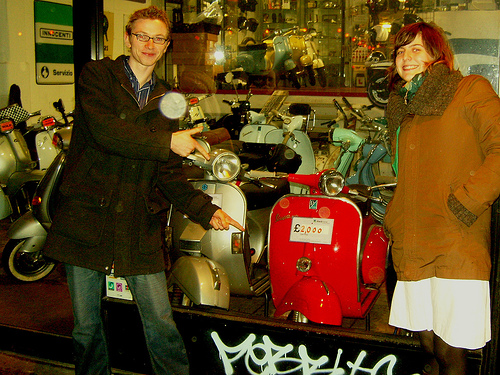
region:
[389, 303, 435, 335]
edge of short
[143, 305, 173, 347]
part of a trouser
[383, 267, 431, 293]
edge of a coat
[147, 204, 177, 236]
part of a pocket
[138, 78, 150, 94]
part of a collar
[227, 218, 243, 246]
part of a finger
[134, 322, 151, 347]
edge of a trouser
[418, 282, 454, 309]
part of a short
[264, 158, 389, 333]
a solid red motorcycle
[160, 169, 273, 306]
a silver motorcycle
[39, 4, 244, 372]
a man standing and pointing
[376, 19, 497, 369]
a woman standing and posing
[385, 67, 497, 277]
a brown winter jacket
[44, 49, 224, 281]
a brown winter jacket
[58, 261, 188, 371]
a pair of men's blue jeans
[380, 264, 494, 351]
a woman's white skirt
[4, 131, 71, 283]
a park silver motorcycle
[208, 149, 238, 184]
a motorcycle headlight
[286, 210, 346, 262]
The number tow thousand.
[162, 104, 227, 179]
The right hand of a man shaped like a gun while pointing.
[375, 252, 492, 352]
A white skirt worn by a woman.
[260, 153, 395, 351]
A red scooter for sale.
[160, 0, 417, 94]
A mirror hanging on the wall.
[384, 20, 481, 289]
The light brown coat worn by a woman.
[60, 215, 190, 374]
A pair of blue jeans being worn by a man.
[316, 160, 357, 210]
The headlight of the red scooter.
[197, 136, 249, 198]
The headlight of the scooter next to the red one.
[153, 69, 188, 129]
The random white circle that appears on top of the coat of the man.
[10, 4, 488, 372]
two people posing for the camera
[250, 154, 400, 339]
a red moped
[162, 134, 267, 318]
a silver moped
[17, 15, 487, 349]
a scene inside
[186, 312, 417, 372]
some white graffiti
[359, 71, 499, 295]
a brown jacket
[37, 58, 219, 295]
a black jacket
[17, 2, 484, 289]
multiple items on the background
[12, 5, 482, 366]
a scene inside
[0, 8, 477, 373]
two people here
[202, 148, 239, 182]
the front light on a vintage scooter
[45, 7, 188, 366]
a man pointing at a scooter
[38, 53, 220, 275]
a brown coat on a man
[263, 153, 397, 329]
a red vintage scooter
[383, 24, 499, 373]
a woman in a scooter store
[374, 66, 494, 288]
a heavy brown coat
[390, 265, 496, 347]
a white skirt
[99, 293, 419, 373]
a black panel with graffiti on it.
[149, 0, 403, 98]
a mirror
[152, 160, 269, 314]
a silver vintage scooter